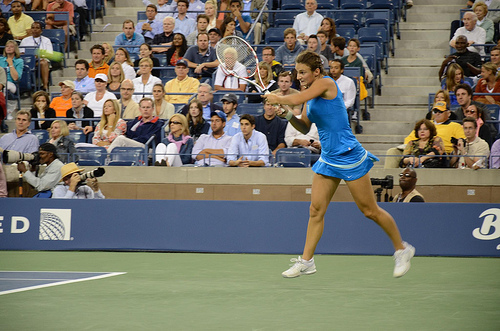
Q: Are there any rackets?
A: Yes, there is a racket.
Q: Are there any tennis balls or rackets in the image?
A: Yes, there is a racket.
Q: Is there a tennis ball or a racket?
A: Yes, there is a racket.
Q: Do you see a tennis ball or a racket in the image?
A: Yes, there is a racket.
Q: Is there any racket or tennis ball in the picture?
A: Yes, there is a racket.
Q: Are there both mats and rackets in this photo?
A: No, there is a racket but no mats.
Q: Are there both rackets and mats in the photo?
A: No, there is a racket but no mats.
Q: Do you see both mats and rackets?
A: No, there is a racket but no mats.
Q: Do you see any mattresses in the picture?
A: No, there are no mattresses.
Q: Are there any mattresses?
A: No, there are no mattresses.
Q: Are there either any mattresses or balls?
A: No, there are no mattresses or balls.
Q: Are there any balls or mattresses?
A: No, there are no mattresses or balls.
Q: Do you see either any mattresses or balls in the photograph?
A: No, there are no mattresses or balls.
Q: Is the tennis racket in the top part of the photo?
A: Yes, the tennis racket is in the top of the image.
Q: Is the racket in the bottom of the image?
A: No, the racket is in the top of the image.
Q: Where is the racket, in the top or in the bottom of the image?
A: The racket is in the top of the image.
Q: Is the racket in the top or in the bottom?
A: The racket is in the top of the image.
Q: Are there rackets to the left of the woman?
A: Yes, there is a racket to the left of the woman.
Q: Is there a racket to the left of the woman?
A: Yes, there is a racket to the left of the woman.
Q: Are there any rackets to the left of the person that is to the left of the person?
A: Yes, there is a racket to the left of the woman.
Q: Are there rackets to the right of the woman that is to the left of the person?
A: No, the racket is to the left of the woman.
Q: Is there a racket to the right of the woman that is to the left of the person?
A: No, the racket is to the left of the woman.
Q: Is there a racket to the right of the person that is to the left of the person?
A: No, the racket is to the left of the woman.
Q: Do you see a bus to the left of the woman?
A: No, there is a racket to the left of the woman.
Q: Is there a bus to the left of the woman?
A: No, there is a racket to the left of the woman.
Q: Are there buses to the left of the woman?
A: No, there is a racket to the left of the woman.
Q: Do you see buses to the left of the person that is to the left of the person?
A: No, there is a racket to the left of the woman.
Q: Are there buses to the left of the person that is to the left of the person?
A: No, there is a racket to the left of the woman.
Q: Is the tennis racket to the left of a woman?
A: Yes, the tennis racket is to the left of a woman.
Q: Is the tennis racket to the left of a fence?
A: No, the tennis racket is to the left of a woman.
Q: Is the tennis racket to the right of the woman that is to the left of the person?
A: No, the tennis racket is to the left of the woman.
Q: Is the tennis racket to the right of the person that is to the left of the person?
A: No, the tennis racket is to the left of the woman.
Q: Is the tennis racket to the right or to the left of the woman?
A: The tennis racket is to the left of the woman.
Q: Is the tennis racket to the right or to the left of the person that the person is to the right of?
A: The tennis racket is to the left of the woman.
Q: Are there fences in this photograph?
A: No, there are no fences.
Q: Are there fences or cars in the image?
A: No, there are no fences or cars.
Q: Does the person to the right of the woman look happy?
A: Yes, the person is happy.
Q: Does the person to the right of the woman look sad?
A: No, the person is happy.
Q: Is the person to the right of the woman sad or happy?
A: The person is happy.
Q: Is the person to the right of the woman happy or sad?
A: The person is happy.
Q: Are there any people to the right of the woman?
A: Yes, there is a person to the right of the woman.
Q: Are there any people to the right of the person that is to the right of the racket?
A: Yes, there is a person to the right of the woman.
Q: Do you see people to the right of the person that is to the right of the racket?
A: Yes, there is a person to the right of the woman.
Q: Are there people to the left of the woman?
A: No, the person is to the right of the woman.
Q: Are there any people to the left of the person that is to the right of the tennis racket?
A: No, the person is to the right of the woman.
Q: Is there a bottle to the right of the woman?
A: No, there is a person to the right of the woman.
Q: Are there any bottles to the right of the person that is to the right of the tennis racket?
A: No, there is a person to the right of the woman.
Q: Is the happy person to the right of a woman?
A: Yes, the person is to the right of a woman.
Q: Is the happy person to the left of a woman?
A: No, the person is to the right of a woman.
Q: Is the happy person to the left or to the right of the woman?
A: The person is to the right of the woman.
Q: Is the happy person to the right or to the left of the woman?
A: The person is to the right of the woman.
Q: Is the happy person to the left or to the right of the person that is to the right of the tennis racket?
A: The person is to the right of the woman.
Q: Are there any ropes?
A: No, there are no ropes.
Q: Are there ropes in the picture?
A: No, there are no ropes.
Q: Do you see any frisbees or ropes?
A: No, there are no ropes or frisbees.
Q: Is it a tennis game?
A: Yes, this is a tennis game.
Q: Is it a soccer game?
A: No, this is a tennis game.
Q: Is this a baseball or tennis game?
A: This is a tennis game.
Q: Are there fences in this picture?
A: No, there are no fences.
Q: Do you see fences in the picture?
A: No, there are no fences.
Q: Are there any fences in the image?
A: No, there are no fences.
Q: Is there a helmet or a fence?
A: No, there are no fences or helmets.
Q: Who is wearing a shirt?
A: The man is wearing a shirt.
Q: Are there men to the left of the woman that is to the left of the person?
A: Yes, there is a man to the left of the woman.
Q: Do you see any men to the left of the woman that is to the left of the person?
A: Yes, there is a man to the left of the woman.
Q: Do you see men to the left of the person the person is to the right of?
A: Yes, there is a man to the left of the woman.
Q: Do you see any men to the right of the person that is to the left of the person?
A: No, the man is to the left of the woman.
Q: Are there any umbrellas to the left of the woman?
A: No, there is a man to the left of the woman.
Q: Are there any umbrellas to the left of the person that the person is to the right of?
A: No, there is a man to the left of the woman.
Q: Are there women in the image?
A: Yes, there is a woman.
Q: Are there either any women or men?
A: Yes, there is a woman.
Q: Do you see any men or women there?
A: Yes, there is a woman.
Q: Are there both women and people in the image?
A: Yes, there are both a woman and people.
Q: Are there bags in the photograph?
A: No, there are no bags.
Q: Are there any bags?
A: No, there are no bags.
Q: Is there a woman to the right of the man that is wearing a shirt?
A: Yes, there is a woman to the right of the man.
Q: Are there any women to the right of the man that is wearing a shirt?
A: Yes, there is a woman to the right of the man.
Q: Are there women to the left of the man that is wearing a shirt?
A: No, the woman is to the right of the man.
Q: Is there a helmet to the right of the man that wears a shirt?
A: No, there is a woman to the right of the man.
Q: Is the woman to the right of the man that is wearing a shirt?
A: Yes, the woman is to the right of the man.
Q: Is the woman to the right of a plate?
A: No, the woman is to the right of the man.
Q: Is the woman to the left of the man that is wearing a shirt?
A: No, the woman is to the right of the man.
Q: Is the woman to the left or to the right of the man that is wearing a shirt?
A: The woman is to the right of the man.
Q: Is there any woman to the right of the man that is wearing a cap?
A: Yes, there is a woman to the right of the man.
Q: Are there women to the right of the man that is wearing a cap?
A: Yes, there is a woman to the right of the man.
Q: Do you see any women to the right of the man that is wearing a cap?
A: Yes, there is a woman to the right of the man.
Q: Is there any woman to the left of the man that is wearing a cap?
A: No, the woman is to the right of the man.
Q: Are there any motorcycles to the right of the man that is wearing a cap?
A: No, there is a woman to the right of the man.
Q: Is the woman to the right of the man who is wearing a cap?
A: Yes, the woman is to the right of the man.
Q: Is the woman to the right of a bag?
A: No, the woman is to the right of the man.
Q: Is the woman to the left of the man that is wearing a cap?
A: No, the woman is to the right of the man.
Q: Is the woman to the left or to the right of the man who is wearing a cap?
A: The woman is to the right of the man.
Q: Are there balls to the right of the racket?
A: No, there is a woman to the right of the racket.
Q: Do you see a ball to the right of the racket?
A: No, there is a woman to the right of the racket.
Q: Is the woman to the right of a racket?
A: Yes, the woman is to the right of a racket.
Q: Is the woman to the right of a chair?
A: No, the woman is to the right of a racket.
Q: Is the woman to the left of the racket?
A: No, the woman is to the right of the racket.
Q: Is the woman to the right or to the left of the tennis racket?
A: The woman is to the right of the tennis racket.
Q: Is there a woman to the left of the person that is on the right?
A: Yes, there is a woman to the left of the person.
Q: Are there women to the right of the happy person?
A: No, the woman is to the left of the person.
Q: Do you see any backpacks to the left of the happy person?
A: No, there is a woman to the left of the person.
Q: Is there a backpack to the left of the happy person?
A: No, there is a woman to the left of the person.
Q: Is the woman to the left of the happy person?
A: Yes, the woman is to the left of the person.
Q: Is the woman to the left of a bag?
A: No, the woman is to the left of the person.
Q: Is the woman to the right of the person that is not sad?
A: No, the woman is to the left of the person.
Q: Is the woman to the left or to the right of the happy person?
A: The woman is to the left of the person.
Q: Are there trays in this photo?
A: No, there are no trays.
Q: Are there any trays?
A: No, there are no trays.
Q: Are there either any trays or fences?
A: No, there are no trays or fences.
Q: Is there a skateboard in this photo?
A: No, there are no skateboards.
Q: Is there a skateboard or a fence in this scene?
A: No, there are no skateboards or fences.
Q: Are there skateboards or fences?
A: No, there are no skateboards or fences.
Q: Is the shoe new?
A: Yes, the shoe is new.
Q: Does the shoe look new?
A: Yes, the shoe is new.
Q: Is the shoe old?
A: No, the shoe is new.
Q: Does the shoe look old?
A: No, the shoe is new.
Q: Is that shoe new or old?
A: The shoe is new.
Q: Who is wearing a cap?
A: The man is wearing a cap.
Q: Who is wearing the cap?
A: The man is wearing a cap.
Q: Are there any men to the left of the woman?
A: Yes, there is a man to the left of the woman.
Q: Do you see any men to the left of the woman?
A: Yes, there is a man to the left of the woman.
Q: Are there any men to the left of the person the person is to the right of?
A: Yes, there is a man to the left of the woman.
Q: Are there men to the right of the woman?
A: No, the man is to the left of the woman.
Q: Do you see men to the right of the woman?
A: No, the man is to the left of the woman.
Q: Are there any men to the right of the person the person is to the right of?
A: No, the man is to the left of the woman.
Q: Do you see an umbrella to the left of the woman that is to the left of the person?
A: No, there is a man to the left of the woman.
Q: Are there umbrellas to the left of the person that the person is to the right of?
A: No, there is a man to the left of the woman.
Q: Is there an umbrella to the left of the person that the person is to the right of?
A: No, there is a man to the left of the woman.